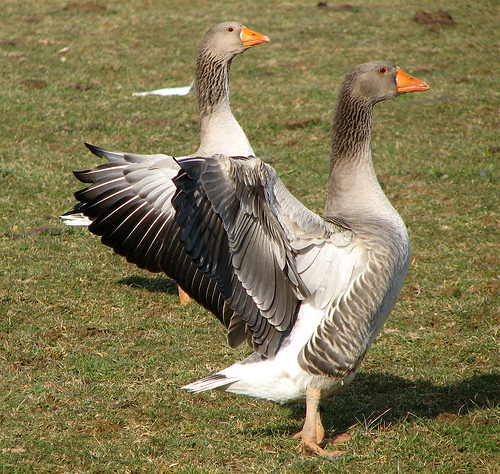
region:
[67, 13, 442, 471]
geese in the grass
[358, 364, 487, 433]
shadow on the ground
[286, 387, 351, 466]
feet of a goose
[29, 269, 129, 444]
green grass by geese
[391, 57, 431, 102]
orange beak of a goose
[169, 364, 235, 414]
tail of a goose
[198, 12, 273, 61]
head of a goose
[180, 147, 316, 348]
wings of a goose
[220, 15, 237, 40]
eye of a goose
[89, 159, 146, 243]
feathers of a goose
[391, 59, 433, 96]
right side of orange goose beak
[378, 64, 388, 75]
one orange colored round goose eye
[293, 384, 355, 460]
two light colored goose legs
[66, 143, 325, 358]
one black tipped extended goose wing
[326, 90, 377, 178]
one gray and black goose neck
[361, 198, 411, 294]
one white and gray goose breast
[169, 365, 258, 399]
light goose tail feathers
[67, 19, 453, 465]
two geese on grassy lawn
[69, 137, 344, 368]
two goose wings outstretched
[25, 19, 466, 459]
sunlit geese standing on grass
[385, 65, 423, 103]
orange beak of duck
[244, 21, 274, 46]
orange beak of goose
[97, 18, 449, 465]
two geese standing together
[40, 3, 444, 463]
two geese next to each other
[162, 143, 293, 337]
wings spread of goose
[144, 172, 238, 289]
black tips to wings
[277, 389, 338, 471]
white and orange feet of goose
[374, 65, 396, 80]
orange and black eye of goos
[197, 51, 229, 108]
black and grey neck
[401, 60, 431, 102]
the beak of a bird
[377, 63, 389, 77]
the eye of a bird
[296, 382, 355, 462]
the legs of a bird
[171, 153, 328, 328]
the wings of a bird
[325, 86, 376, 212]
the long neck of a bird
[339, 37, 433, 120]
the head of a bird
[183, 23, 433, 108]
the two beaks of the two birds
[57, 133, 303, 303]
the wigs of the two birds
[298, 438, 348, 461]
the claws of a bird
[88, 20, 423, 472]
the two birds walking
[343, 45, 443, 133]
head of a bird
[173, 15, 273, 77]
of a bird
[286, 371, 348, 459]
leg of a bird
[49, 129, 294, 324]
wing of a bird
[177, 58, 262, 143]
neck of a bird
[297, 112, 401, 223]
neck of a bird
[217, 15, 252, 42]
eye of a bird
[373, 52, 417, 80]
eye of a bird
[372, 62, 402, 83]
an eye of a bird